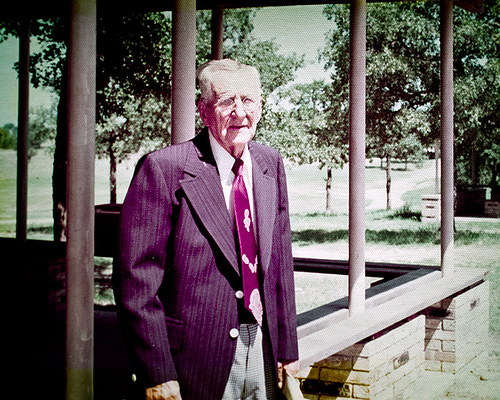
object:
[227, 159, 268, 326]
tie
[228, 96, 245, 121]
nose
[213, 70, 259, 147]
face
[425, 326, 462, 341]
brick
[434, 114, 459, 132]
ground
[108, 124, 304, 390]
suit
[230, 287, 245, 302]
button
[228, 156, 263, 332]
purple tie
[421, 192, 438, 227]
sign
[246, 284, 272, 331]
cone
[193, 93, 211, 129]
ear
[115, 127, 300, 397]
jacket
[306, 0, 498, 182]
trees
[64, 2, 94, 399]
column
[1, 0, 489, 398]
gazebo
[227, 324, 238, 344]
button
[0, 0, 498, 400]
park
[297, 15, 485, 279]
park trail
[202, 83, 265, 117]
glasses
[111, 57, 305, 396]
man